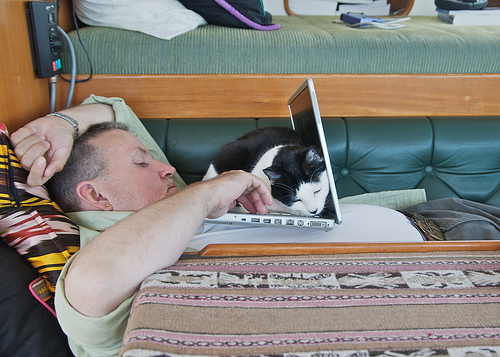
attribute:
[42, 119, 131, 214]
hair — black, grey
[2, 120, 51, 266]
pillow — striped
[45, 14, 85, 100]
wire — blue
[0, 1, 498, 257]
wood — brown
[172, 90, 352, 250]
cat — black and white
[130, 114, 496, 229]
sofa — greenish, leather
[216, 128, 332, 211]
cat — black and white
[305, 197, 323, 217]
nose — small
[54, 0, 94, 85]
wire — black 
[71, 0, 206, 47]
pillow — white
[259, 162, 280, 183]
ear — right ear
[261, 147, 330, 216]
cat's face — black and white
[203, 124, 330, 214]
cat — black, white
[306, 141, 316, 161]
ear — left ear